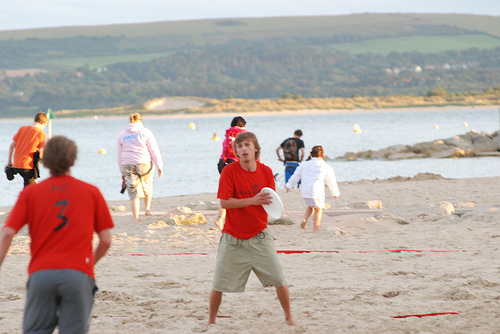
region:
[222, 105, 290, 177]
the head of a man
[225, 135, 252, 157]
the eyes of a man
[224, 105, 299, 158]
the hair of a man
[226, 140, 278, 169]
the nose of a man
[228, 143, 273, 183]
the chin of a man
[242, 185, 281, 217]
the hand of a man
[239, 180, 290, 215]
the fingers of a man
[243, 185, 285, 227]
a frisbee in a man hand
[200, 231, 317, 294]
a man wearing shorts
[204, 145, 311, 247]
a man wearing a shirt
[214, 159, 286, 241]
man wearing red shirt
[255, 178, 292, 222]
man holding a white frisbee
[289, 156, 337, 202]
person wearing a white jacket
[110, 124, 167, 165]
person wearing a pink jacket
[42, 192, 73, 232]
person with the number three on their shirt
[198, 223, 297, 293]
person wearing khaki colored shorts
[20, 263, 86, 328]
person wearing gray shorts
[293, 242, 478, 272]
red line in the sand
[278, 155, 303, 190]
man wearing blue shorts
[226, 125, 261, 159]
man with blond hair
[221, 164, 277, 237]
Red t-shirt in the photo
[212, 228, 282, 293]
Shorts in the background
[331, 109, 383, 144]
Water in the background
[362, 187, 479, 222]
Rock pebbles in the photo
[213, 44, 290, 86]
Trees in the photo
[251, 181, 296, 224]
A frisbee in the photo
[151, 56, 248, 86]
A forest in the photo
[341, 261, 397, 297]
Sand at the beach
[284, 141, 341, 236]
Girl in the photo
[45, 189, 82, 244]
A number on the t-shirt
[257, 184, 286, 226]
White frisbee in the hands.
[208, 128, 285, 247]
Orange shorts on the boy.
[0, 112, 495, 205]
Water in the background.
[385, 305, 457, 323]
Red line in the sand.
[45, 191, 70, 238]
Number on the shirt.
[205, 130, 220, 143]
Person in the water.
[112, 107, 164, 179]
White sweatshirt on the person.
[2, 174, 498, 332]
Sand on the beach.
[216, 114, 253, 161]
Red shirt on person.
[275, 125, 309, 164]
Black shirt on the person.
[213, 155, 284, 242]
man's shirt is red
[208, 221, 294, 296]
man's pants are brown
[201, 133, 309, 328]
man holding a frisbee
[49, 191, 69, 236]
black number on man's shirt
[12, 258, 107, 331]
man's shorts are gray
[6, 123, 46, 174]
man's shirt is orange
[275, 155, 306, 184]
man's shorts are blue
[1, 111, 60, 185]
person holding black object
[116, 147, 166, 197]
person's shorts are brown